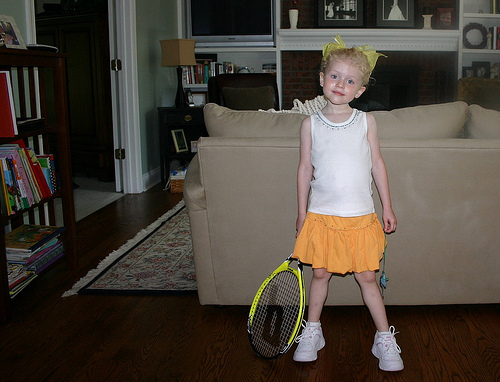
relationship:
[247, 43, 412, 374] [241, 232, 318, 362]
girl holding racket girl has racket racket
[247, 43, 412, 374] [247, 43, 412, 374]
girl is standing girl in room girl holding racket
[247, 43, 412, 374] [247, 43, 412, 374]
girl is standing girl behind girl holding racket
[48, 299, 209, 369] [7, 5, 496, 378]
floor is hardwood floor wood livingroom has wood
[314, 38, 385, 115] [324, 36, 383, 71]
girl has bow bow yellow bow in hair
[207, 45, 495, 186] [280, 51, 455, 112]
sofa faces brick sofa faces fireplace fireplace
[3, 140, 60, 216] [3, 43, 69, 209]
books are upright books on shelf shelf has books.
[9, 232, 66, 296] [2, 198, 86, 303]
books lay books lay flat books on bottom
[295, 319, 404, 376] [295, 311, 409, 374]
girl wears shoes girl wears white girl wears socks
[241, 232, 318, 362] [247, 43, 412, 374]
racket racket has yellow girl holds racket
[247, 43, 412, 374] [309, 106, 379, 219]
girl is little little girl in shirt shirt is yellow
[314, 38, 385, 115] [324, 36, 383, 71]
girl has bow bow in hair yellow bow in hair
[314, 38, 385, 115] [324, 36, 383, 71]
she has bow she has yellow bow is yellow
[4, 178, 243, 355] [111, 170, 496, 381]
room has hardwood floors are hardwood room has floors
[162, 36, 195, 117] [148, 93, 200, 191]
lamp in table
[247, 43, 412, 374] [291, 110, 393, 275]
girl is cute in outfit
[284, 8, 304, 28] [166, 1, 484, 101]
vase on mantel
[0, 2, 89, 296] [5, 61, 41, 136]
bookshelf filled books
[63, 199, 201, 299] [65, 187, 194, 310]
rug on floor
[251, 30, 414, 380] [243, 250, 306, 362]
girl holding racket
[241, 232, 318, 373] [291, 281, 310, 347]
racket has rim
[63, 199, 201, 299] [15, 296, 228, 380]
rug on floor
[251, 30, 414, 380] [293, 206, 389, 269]
girl wearing skirt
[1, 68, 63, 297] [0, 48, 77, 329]
books on shelf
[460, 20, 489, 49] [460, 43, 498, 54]
wreath on shelf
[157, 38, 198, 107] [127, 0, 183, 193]
table lamp near wall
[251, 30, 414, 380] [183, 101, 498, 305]
girl in front of couch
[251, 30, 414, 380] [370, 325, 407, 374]
girl wearing shoe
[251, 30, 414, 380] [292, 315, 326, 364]
girl wearing shoe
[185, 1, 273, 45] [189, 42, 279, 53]
television on shelf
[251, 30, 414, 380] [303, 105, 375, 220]
girl wearing tank top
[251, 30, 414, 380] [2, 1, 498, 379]
girl in living room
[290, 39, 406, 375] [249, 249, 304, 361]
she holding tennis racket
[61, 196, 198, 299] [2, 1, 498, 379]
area rug in living room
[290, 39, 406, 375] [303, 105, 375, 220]
she wearing tank top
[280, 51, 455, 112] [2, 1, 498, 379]
fireplace in living room